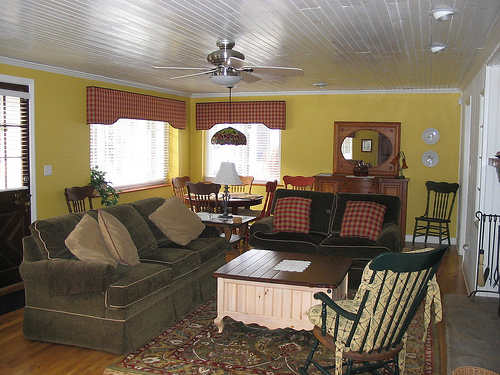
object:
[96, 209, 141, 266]
pillows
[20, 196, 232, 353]
couch